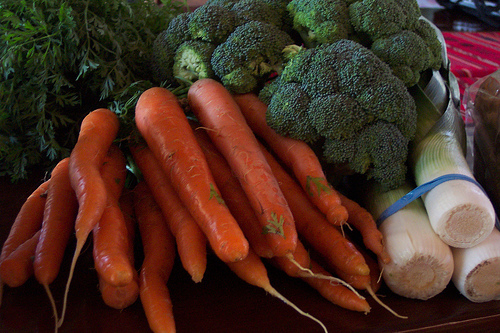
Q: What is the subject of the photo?
A: Food.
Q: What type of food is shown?
A: Vegetables.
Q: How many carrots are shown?
A: Nineteen.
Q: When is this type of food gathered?
A: Harvest.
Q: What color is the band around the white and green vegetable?
A: Blue.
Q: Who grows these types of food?
A: Farmer.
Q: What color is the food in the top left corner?
A: Green.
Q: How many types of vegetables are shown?
A: Four.